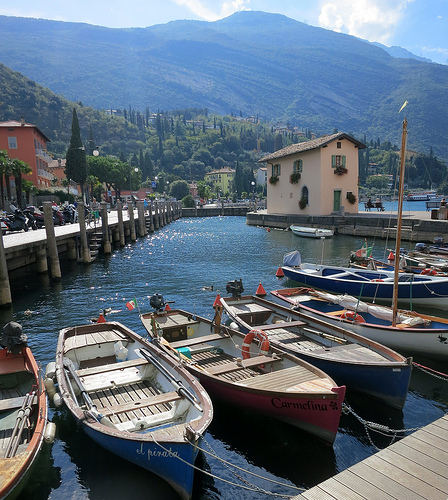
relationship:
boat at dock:
[48, 322, 202, 480] [337, 466, 446, 500]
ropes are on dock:
[342, 404, 410, 444] [337, 466, 446, 500]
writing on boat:
[133, 443, 181, 459] [48, 322, 202, 480]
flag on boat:
[127, 293, 148, 320] [143, 304, 342, 434]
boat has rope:
[48, 322, 202, 480] [187, 429, 292, 487]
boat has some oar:
[48, 322, 202, 480] [63, 358, 101, 416]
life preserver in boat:
[238, 328, 276, 377] [143, 304, 342, 434]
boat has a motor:
[143, 304, 342, 434] [136, 289, 176, 328]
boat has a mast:
[281, 286, 443, 350] [388, 107, 413, 323]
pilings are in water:
[72, 198, 95, 262] [180, 217, 259, 281]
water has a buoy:
[180, 217, 259, 281] [258, 226, 274, 236]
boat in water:
[48, 322, 202, 480] [180, 217, 259, 281]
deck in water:
[318, 414, 436, 493] [180, 217, 259, 281]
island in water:
[4, 19, 444, 487] [180, 217, 259, 281]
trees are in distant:
[111, 105, 265, 195] [9, 16, 436, 70]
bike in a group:
[28, 207, 61, 228] [14, 199, 102, 228]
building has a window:
[258, 135, 367, 227] [331, 151, 352, 172]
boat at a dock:
[48, 322, 202, 480] [337, 466, 446, 500]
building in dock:
[258, 135, 367, 227] [0, 120, 448, 500]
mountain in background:
[2, 14, 441, 187] [9, 16, 436, 70]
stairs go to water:
[82, 231, 102, 265] [180, 217, 259, 281]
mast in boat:
[390, 119, 407, 327] [281, 286, 443, 350]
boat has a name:
[48, 322, 202, 480] [133, 443, 181, 459]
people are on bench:
[367, 198, 382, 203] [362, 196, 386, 213]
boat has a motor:
[48, 322, 202, 480] [136, 289, 176, 328]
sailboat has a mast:
[281, 286, 443, 350] [388, 107, 413, 323]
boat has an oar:
[48, 322, 202, 480] [63, 358, 101, 416]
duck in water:
[199, 283, 215, 294] [180, 217, 259, 281]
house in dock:
[258, 135, 367, 227] [0, 120, 448, 500]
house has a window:
[258, 135, 367, 227] [331, 151, 352, 172]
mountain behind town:
[2, 14, 441, 187] [1, 118, 441, 337]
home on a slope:
[115, 104, 267, 136] [0, 62, 233, 184]